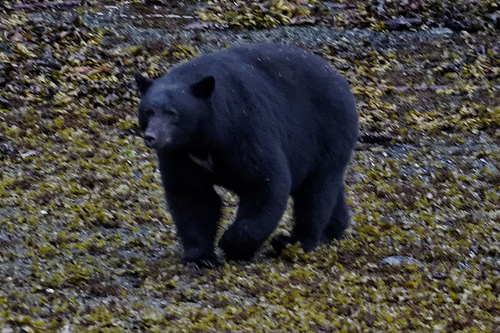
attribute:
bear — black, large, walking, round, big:
[132, 40, 360, 267]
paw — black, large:
[181, 249, 218, 269]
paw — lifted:
[220, 238, 254, 265]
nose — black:
[143, 129, 155, 149]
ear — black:
[190, 77, 216, 101]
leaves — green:
[54, 141, 171, 263]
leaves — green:
[298, 252, 433, 333]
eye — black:
[163, 109, 177, 119]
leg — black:
[231, 167, 292, 244]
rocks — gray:
[176, 300, 201, 317]